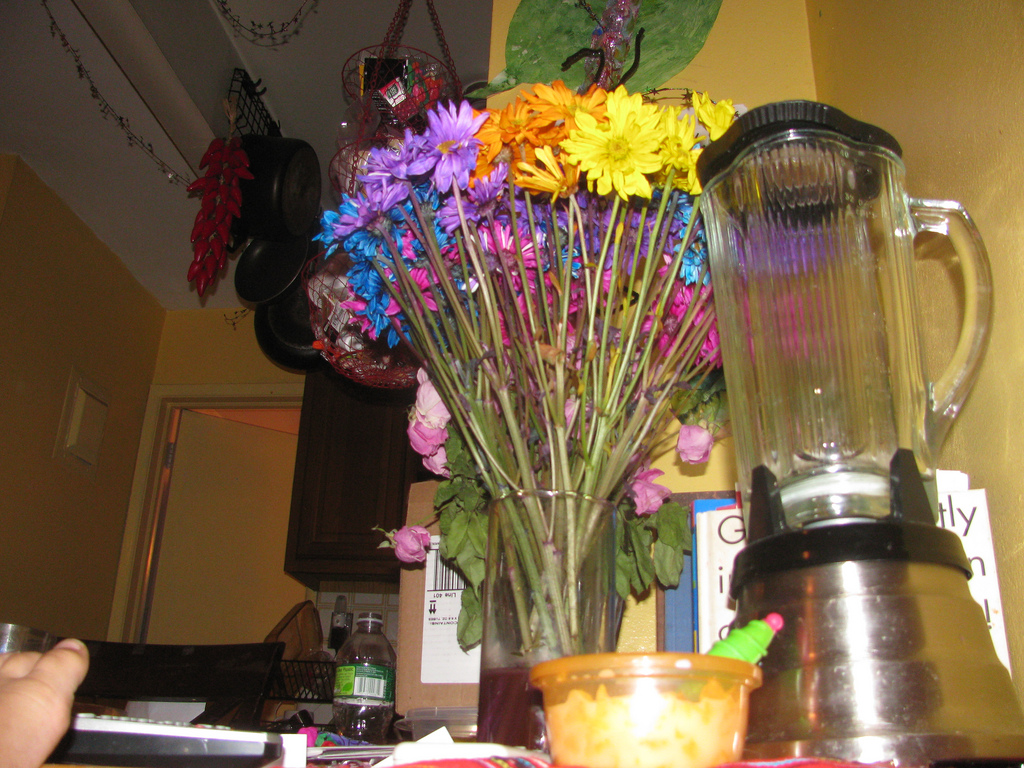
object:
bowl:
[529, 650, 765, 763]